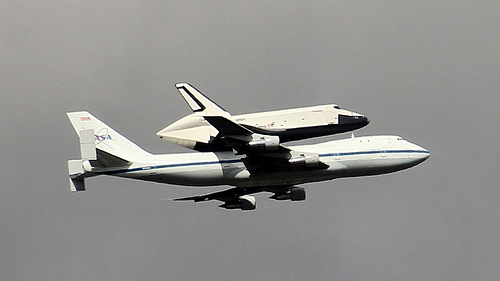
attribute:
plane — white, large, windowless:
[66, 110, 431, 209]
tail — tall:
[66, 110, 153, 164]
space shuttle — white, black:
[156, 81, 369, 151]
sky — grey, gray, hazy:
[0, 0, 499, 280]